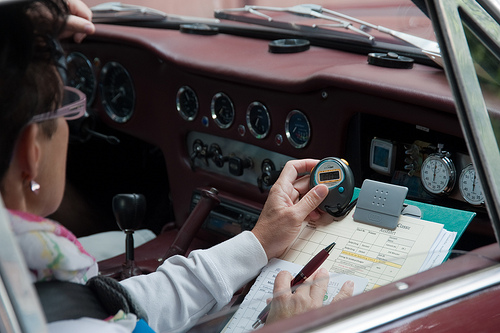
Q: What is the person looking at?
A: Stop watchs.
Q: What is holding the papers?
A: Clipboard.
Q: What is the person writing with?
A: Pen.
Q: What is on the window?
A: Windshield wiper.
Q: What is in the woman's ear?
A: Earring.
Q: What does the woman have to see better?
A: Glasses.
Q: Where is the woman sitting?
A: In a car.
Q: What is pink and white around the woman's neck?
A: A scarf.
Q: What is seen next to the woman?
A: A gear shifter.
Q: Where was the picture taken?
A: In a car.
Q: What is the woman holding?
A: A watch.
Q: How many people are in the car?
A: 2 people are in the car.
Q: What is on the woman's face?
A: She is wearing glasses.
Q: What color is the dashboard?
A: The dashboard is burgundy.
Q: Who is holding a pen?
A: The woman.